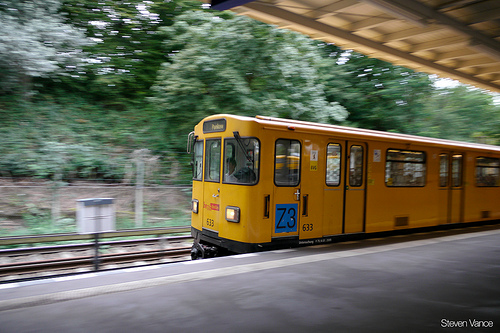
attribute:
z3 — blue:
[269, 202, 299, 236]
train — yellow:
[181, 102, 498, 242]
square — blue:
[271, 197, 307, 232]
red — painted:
[202, 203, 224, 217]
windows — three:
[190, 140, 256, 185]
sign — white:
[73, 192, 115, 236]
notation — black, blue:
[269, 194, 291, 224]